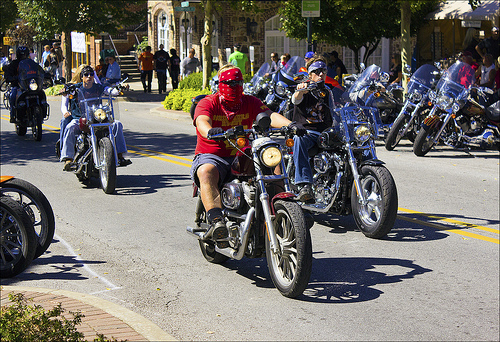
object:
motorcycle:
[187, 124, 315, 299]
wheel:
[259, 199, 311, 300]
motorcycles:
[383, 60, 485, 150]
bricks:
[70, 314, 125, 339]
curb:
[2, 280, 162, 340]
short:
[190, 149, 237, 189]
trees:
[279, 3, 433, 73]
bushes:
[164, 89, 185, 111]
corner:
[150, 97, 195, 120]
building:
[143, 2, 418, 78]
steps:
[117, 53, 141, 83]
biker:
[189, 62, 297, 233]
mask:
[218, 65, 243, 103]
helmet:
[80, 65, 96, 77]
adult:
[135, 44, 156, 96]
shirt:
[138, 51, 157, 70]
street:
[0, 84, 498, 340]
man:
[290, 61, 364, 204]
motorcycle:
[267, 92, 399, 240]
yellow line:
[5, 109, 499, 246]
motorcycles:
[413, 56, 497, 157]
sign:
[300, 0, 320, 19]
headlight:
[262, 146, 283, 167]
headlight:
[354, 124, 370, 142]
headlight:
[92, 108, 107, 122]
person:
[153, 44, 172, 95]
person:
[166, 48, 182, 89]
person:
[227, 44, 248, 77]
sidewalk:
[107, 77, 180, 96]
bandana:
[216, 66, 244, 103]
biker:
[58, 65, 134, 171]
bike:
[58, 77, 131, 195]